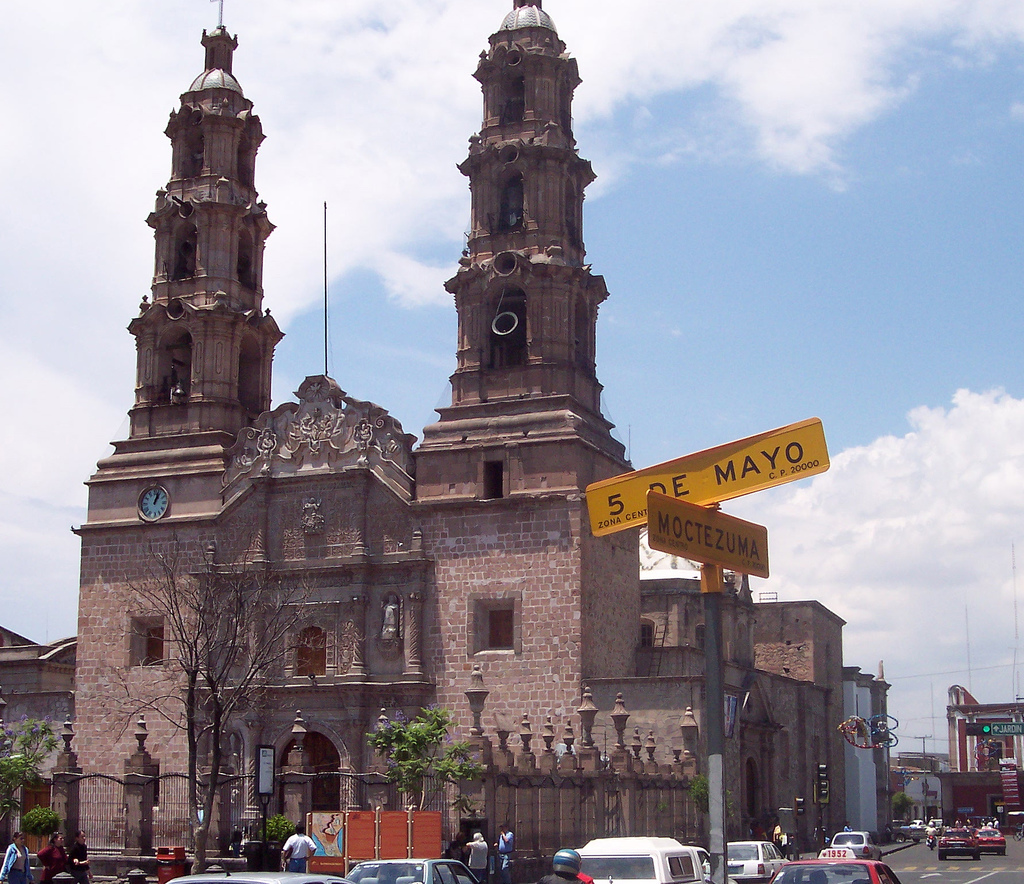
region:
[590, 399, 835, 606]
yellow and black street signs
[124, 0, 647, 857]
large brick church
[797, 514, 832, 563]
white clouds in blue sky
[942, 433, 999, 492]
white clouds in blue sky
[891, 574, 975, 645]
white clouds in blue sky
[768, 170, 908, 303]
white clouds in blue sky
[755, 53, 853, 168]
white clouds in blue sky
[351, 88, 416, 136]
white clouds in blue sky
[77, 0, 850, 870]
an old church building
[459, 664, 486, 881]
a column with a decorative cap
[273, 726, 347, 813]
an arched entryway to the building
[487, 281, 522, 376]
a bell in the tower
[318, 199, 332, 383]
a pole on the roof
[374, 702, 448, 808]
a small tree outside the building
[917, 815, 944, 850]
a person riding a bike of some kind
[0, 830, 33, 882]
a woman in a blue sweater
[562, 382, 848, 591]
yellow and black street sings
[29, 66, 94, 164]
white clouds in blue sky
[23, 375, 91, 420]
white clouds in blue sky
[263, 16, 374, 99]
white clouds in blue sky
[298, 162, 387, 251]
white clouds in blue sky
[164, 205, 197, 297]
a window on a building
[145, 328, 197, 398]
a window on a building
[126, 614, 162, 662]
a window on a building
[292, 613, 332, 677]
a window on a building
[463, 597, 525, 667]
a window on a building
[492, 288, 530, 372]
a window on a building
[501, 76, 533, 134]
a window on a building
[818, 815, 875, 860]
a car on a street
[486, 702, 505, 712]
A brick in a building.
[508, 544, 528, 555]
A brick in a building.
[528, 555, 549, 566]
A brick in a building.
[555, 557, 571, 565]
A brick in a building.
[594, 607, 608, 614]
A brick in a building.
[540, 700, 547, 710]
A brick in a building.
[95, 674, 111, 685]
A brick in a building.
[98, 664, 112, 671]
A brick in a building.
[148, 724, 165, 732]
A brick in a building.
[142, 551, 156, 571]
A brick in a building.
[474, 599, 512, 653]
A window on a building.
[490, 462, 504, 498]
A window on a building.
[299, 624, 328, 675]
A window on a building.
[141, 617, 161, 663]
A window on a building.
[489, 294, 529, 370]
A window on a building.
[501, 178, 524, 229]
A window on a building.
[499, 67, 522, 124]
A window on a building.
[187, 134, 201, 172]
A window on a building.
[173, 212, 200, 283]
A window on a building.